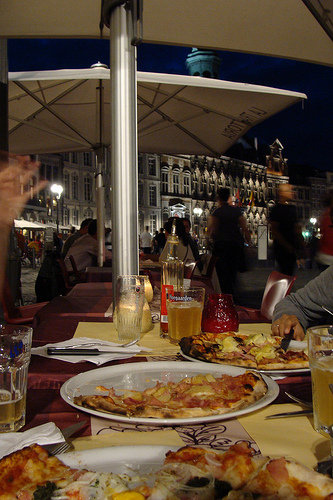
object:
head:
[164, 217, 185, 239]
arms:
[159, 238, 180, 264]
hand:
[0, 148, 50, 225]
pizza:
[72, 370, 269, 418]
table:
[2, 315, 331, 497]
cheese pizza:
[19, 465, 316, 493]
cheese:
[78, 475, 118, 495]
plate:
[70, 364, 219, 389]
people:
[158, 216, 203, 274]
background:
[13, 158, 325, 266]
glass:
[116, 276, 145, 342]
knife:
[44, 343, 152, 359]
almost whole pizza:
[179, 328, 317, 367]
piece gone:
[51, 440, 167, 478]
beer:
[166, 287, 205, 344]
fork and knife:
[46, 338, 142, 357]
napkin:
[29, 337, 157, 367]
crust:
[79, 398, 165, 421]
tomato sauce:
[4, 461, 20, 495]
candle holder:
[202, 292, 239, 334]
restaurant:
[2, 156, 332, 498]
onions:
[185, 476, 210, 488]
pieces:
[96, 384, 158, 414]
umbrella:
[6, 73, 307, 155]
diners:
[64, 219, 102, 282]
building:
[156, 160, 282, 233]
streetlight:
[52, 184, 64, 199]